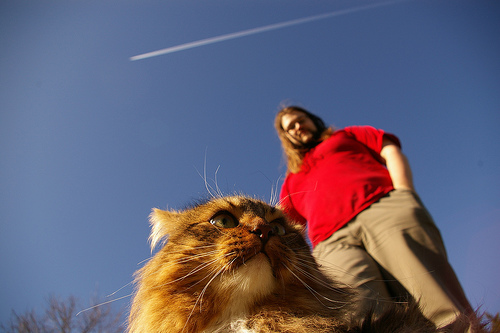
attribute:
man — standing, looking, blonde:
[267, 98, 481, 332]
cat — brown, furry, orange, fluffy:
[117, 190, 488, 332]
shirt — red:
[272, 129, 418, 211]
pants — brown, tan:
[299, 202, 478, 332]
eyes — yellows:
[203, 208, 291, 237]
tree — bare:
[3, 288, 138, 332]